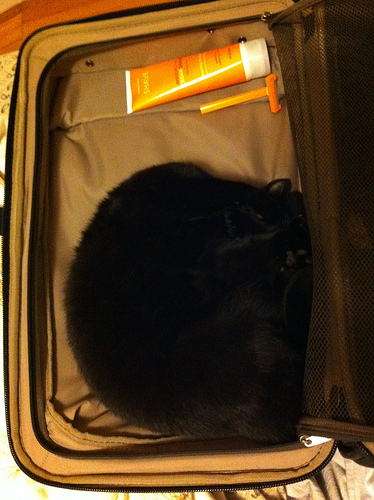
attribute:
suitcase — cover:
[16, 17, 372, 483]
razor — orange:
[194, 70, 285, 121]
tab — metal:
[305, 434, 331, 444]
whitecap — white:
[236, 38, 273, 80]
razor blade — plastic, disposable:
[189, 59, 287, 135]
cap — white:
[231, 31, 274, 82]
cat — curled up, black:
[42, 137, 337, 453]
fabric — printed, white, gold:
[3, 434, 176, 497]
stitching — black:
[48, 376, 129, 443]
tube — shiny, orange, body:
[117, 37, 277, 112]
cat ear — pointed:
[260, 176, 292, 199]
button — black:
[84, 58, 96, 70]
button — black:
[206, 28, 216, 36]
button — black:
[234, 33, 250, 45]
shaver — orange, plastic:
[198, 77, 284, 118]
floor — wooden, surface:
[2, 0, 185, 54]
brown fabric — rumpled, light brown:
[316, 452, 361, 491]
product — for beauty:
[126, 38, 269, 112]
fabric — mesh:
[309, 6, 373, 422]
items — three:
[103, 36, 307, 147]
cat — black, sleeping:
[57, 159, 317, 456]